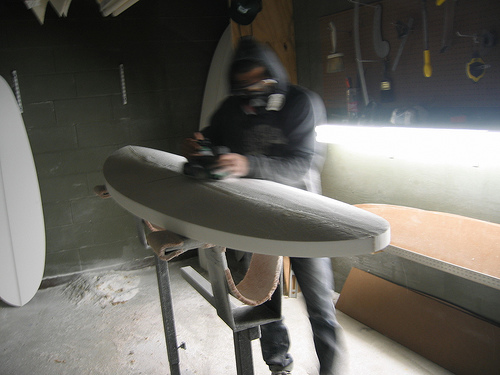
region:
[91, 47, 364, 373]
man working on surboard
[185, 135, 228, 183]
electric sander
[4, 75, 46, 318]
surfboard against the wall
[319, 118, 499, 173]
light above the work area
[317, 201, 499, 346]
work area behind the man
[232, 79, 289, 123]
protective mask man is wearing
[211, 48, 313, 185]
hooded jacket man is wearing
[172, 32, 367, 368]
this is a person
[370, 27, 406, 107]
a tool hanging on the wall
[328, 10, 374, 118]
a tool hanging on the wall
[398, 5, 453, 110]
a tool hanging on the wall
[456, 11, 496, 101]
a tool hanging on the wall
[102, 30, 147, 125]
a tool hanging on the wall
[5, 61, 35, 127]
a tool hanging on the wall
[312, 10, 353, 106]
a tool hanging on the wall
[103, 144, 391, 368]
surfboard lifted onto frame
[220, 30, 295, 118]
person with eyes, nose and head covered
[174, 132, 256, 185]
hands holding black sander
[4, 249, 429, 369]
gray floor covered with dust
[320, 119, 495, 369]
light shining over cushioned bench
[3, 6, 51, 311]
white surfboard leaning against wall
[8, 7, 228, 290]
dark cinder-block wall with metal strips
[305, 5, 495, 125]
tools hanging on dark wall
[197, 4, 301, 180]
person in front of surfboard and yellow panel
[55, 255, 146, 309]
pile of white dust on floor near wall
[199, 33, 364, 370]
A man is wearing a mask.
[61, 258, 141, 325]
A pile of dust near the wall.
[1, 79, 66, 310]
A white surfboard leaned up against the wall.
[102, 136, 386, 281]
A surfboard being made in a shop.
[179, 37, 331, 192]
The man is wearing a black sweater.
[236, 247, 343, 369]
The man is wearing black pants.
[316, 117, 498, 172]
A tube light is lighting the room.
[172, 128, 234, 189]
The man is using a sander on the surfboard.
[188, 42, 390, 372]
The man is holding a sander with two hands.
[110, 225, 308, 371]
The surfboard in on top of a stand.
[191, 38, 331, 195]
the hoodie is black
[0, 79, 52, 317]
surfboard on the wall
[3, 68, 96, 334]
surfboard on the wall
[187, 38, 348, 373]
A person with a respirator on and black hoodie.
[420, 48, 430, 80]
Long yellow handle on a tool hanging on wall.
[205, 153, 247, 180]
Left hand on a man sanding.